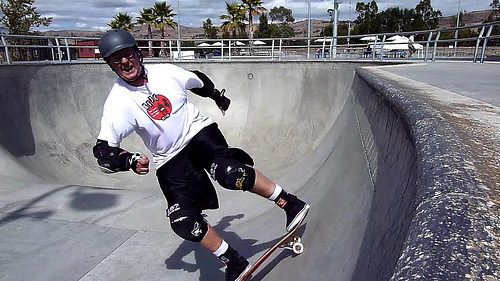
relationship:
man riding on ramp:
[92, 31, 307, 280] [242, 60, 490, 280]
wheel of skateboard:
[290, 241, 306, 254] [243, 213, 310, 280]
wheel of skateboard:
[292, 235, 302, 244] [243, 213, 310, 280]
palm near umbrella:
[240, 1, 265, 40] [251, 37, 265, 46]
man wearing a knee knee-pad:
[92, 31, 307, 280] [216, 166, 255, 190]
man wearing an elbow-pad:
[92, 31, 307, 280] [190, 68, 215, 96]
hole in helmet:
[113, 29, 118, 32] [98, 29, 138, 63]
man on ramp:
[92, 31, 307, 280] [242, 60, 490, 280]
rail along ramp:
[2, 20, 499, 66] [242, 60, 490, 280]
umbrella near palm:
[214, 42, 227, 48] [218, 1, 249, 39]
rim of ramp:
[354, 67, 499, 281] [242, 60, 490, 280]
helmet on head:
[98, 29, 138, 63] [100, 31, 141, 82]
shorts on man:
[157, 124, 253, 208] [92, 31, 307, 280]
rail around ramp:
[2, 20, 499, 66] [242, 60, 490, 280]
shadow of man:
[165, 215, 289, 280] [92, 31, 307, 280]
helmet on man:
[98, 29, 138, 63] [92, 31, 307, 280]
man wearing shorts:
[92, 31, 307, 280] [157, 124, 253, 208]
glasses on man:
[109, 50, 137, 66] [92, 31, 307, 280]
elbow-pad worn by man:
[93, 139, 124, 174] [92, 31, 307, 280]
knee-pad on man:
[166, 205, 207, 241] [92, 31, 307, 280]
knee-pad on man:
[206, 156, 256, 192] [92, 31, 307, 280]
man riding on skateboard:
[92, 31, 307, 280] [243, 213, 310, 280]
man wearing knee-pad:
[92, 31, 307, 280] [166, 205, 207, 241]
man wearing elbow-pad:
[92, 31, 307, 280] [93, 139, 124, 174]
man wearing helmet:
[92, 31, 307, 280] [98, 29, 138, 63]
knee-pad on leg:
[166, 205, 207, 241] [170, 210, 248, 272]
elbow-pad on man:
[190, 68, 215, 96] [92, 31, 307, 280]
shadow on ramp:
[165, 215, 289, 280] [242, 60, 490, 280]